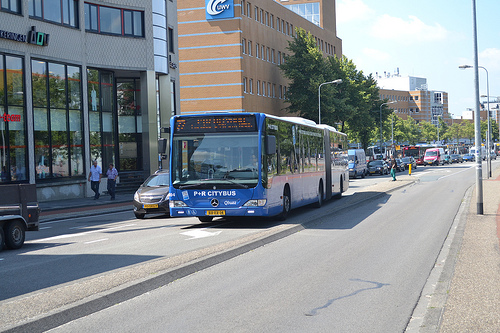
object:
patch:
[305, 275, 389, 317]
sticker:
[472, 145, 482, 171]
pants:
[388, 168, 397, 179]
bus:
[167, 109, 352, 222]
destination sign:
[172, 115, 262, 136]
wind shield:
[171, 135, 260, 185]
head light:
[258, 199, 268, 210]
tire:
[281, 193, 291, 216]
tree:
[274, 25, 344, 125]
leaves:
[305, 65, 324, 82]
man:
[86, 157, 102, 200]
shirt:
[86, 163, 103, 182]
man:
[105, 163, 119, 200]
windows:
[299, 124, 317, 173]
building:
[0, 0, 183, 207]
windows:
[4, 50, 28, 108]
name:
[0, 24, 51, 51]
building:
[177, 0, 343, 117]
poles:
[471, 0, 484, 217]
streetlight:
[455, 63, 474, 70]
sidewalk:
[401, 182, 481, 331]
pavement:
[8, 194, 135, 225]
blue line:
[176, 93, 246, 103]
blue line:
[180, 80, 242, 90]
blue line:
[178, 55, 246, 64]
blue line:
[180, 41, 242, 50]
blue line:
[175, 29, 242, 38]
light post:
[315, 82, 333, 124]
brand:
[208, 197, 221, 208]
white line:
[84, 236, 111, 246]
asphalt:
[83, 255, 127, 263]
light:
[457, 63, 473, 71]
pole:
[475, 60, 493, 179]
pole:
[406, 162, 413, 176]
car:
[132, 168, 176, 218]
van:
[347, 146, 368, 179]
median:
[0, 179, 417, 332]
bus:
[400, 144, 436, 164]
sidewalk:
[7, 183, 137, 224]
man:
[390, 155, 400, 182]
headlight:
[241, 198, 259, 208]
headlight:
[171, 201, 188, 209]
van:
[423, 145, 446, 168]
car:
[450, 152, 466, 163]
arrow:
[179, 226, 227, 242]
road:
[0, 156, 498, 332]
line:
[437, 167, 474, 182]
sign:
[203, 0, 236, 22]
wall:
[177, 0, 244, 114]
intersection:
[348, 157, 500, 196]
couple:
[85, 157, 121, 203]